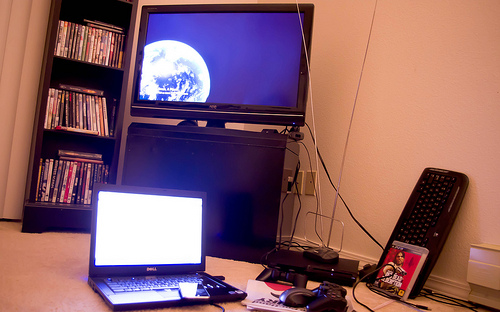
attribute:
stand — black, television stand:
[169, 89, 314, 143]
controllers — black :
[282, 264, 354, 306]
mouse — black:
[278, 286, 313, 307]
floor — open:
[12, 223, 64, 283]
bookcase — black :
[27, 3, 132, 229]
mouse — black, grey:
[250, 281, 331, 309]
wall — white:
[291, 0, 497, 300]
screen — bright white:
[93, 190, 201, 265]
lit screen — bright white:
[95, 189, 201, 264]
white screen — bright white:
[96, 187, 200, 264]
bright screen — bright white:
[93, 190, 201, 264]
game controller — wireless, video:
[302, 277, 352, 310]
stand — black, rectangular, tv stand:
[117, 122, 299, 263]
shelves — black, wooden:
[17, 15, 125, 263]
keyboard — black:
[366, 167, 469, 298]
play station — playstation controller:
[304, 278, 346, 310]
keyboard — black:
[362, 155, 474, 310]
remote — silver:
[247, 283, 301, 310]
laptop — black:
[87, 181, 247, 310]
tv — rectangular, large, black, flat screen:
[127, 2, 314, 127]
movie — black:
[371, 237, 431, 302]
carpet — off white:
[1, 221, 484, 311]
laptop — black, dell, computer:
[88, 189, 245, 304]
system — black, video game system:
[266, 242, 363, 287]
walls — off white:
[321, 1, 498, 283]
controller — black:
[304, 280, 347, 310]